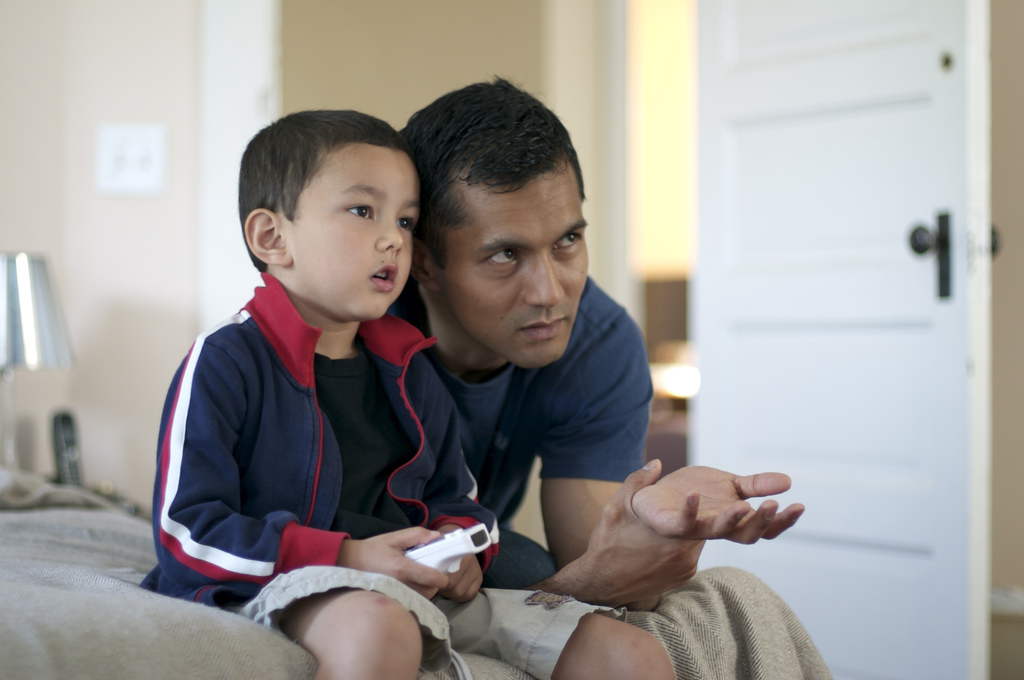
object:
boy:
[139, 107, 678, 680]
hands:
[521, 458, 805, 611]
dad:
[400, 77, 805, 609]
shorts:
[221, 565, 629, 680]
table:
[0, 464, 137, 514]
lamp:
[0, 251, 77, 373]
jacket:
[142, 272, 503, 607]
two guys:
[142, 74, 808, 680]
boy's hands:
[336, 523, 484, 603]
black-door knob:
[911, 227, 931, 253]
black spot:
[942, 54, 950, 66]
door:
[688, 0, 995, 680]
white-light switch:
[95, 127, 167, 192]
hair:
[239, 109, 414, 272]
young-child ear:
[238, 204, 292, 276]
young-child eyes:
[339, 192, 419, 238]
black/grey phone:
[54, 413, 84, 486]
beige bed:
[0, 472, 840, 680]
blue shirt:
[378, 276, 654, 523]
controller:
[405, 523, 492, 575]